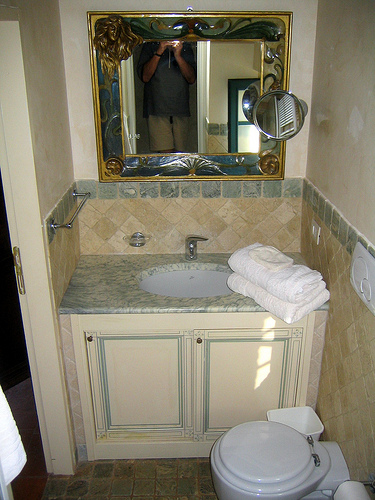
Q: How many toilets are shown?
A: One.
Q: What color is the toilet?
A: White.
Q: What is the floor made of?
A: Tile.